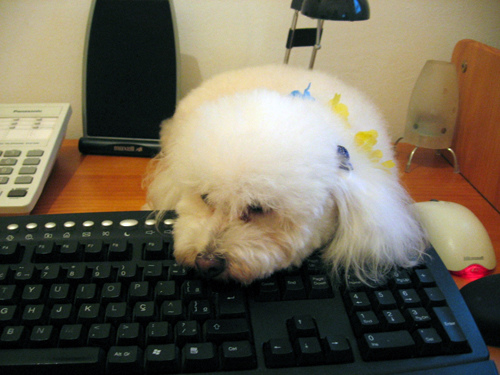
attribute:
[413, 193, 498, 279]
mouse — by Microsoft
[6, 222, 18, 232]
button — small, silver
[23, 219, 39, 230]
button — small, silver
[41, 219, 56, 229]
button — small, silver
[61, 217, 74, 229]
button — small, silver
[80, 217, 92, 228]
button — small, silver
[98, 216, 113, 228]
button — small, silver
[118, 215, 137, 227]
button — small, silver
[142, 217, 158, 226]
button — small, silver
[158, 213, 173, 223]
button — small, silver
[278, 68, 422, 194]
flowers — yellow and blue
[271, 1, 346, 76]
lamp — for Desk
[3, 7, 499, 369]
desk — brown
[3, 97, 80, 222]
telephone — beige, old-looking, white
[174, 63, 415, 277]
dog — white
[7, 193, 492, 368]
keyboard — black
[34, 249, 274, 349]
keys — black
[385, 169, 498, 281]
mouse — White, computer's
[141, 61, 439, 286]
dog — black, white, fluffy 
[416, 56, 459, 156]
table lamp — clear, frosted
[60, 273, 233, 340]
buttons — black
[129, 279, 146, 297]
key — black 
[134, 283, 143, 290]
letter — white 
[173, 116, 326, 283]
face — white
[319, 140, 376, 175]
bow — purple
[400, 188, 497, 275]
mouse — white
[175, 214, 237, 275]
nose — black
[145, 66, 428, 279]
dog — small, fluffy, white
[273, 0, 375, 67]
lamp — telescoping, hooded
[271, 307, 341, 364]
keys — directional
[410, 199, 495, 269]
mouse — white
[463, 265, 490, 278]
light — red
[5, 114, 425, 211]
desk top — wooden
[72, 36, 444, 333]
dog — white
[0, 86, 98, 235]
telephone — landline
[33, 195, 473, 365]
keyboard — black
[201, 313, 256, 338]
key — black, long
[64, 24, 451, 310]
dog —  small, poodle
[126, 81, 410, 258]
dog — fluffy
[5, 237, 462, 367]
buttons — silver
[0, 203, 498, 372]
keyboard — black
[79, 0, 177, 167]
speaker — computer's, black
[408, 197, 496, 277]
mouse — white, optical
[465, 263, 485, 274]
light — red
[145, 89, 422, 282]
head — dog's 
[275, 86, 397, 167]
collar — blue and yellow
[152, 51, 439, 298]
fur — white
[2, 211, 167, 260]
buttons — silver